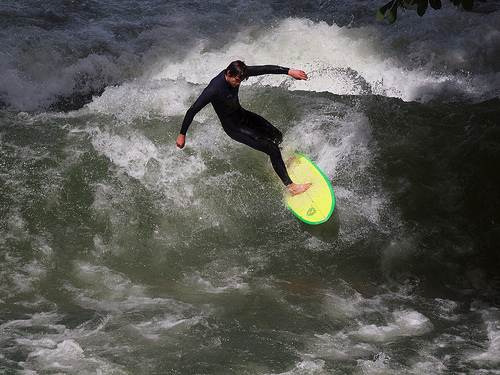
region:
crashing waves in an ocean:
[33, 28, 183, 320]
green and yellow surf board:
[261, 139, 356, 257]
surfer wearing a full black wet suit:
[137, 50, 363, 232]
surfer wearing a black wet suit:
[182, 45, 331, 235]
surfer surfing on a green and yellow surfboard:
[174, 43, 367, 260]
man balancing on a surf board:
[140, 41, 353, 243]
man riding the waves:
[166, 47, 368, 274]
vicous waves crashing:
[104, 10, 449, 142]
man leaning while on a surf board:
[173, 46, 375, 279]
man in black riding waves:
[149, 28, 423, 349]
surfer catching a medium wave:
[174, 52, 339, 232]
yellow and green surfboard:
[268, 145, 340, 230]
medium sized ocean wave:
[17, 89, 165, 250]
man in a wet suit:
[167, 54, 312, 197]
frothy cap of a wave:
[27, 99, 164, 251]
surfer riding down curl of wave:
[46, 59, 438, 309]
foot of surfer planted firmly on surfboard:
[280, 145, 337, 236]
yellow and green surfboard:
[282, 195, 345, 264]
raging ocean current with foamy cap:
[319, 17, 485, 122]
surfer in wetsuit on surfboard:
[168, 57, 349, 242]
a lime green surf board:
[275, 153, 337, 228]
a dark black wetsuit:
[167, 63, 297, 186]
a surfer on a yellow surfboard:
[172, 61, 339, 231]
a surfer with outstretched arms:
[156, 52, 323, 194]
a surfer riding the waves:
[93, 39, 338, 243]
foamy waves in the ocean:
[11, 9, 478, 109]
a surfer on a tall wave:
[18, 58, 496, 266]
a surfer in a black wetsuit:
[165, 56, 342, 228]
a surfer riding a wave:
[161, 50, 344, 240]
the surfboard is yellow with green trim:
[266, 138, 337, 241]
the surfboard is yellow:
[264, 176, 359, 225]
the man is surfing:
[163, 23, 401, 276]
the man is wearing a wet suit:
[159, 41, 376, 253]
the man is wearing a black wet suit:
[101, 20, 397, 272]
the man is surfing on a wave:
[116, 38, 446, 263]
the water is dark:
[359, 61, 420, 178]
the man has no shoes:
[131, 31, 381, 280]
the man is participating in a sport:
[146, 64, 363, 261]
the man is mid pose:
[61, 41, 448, 259]